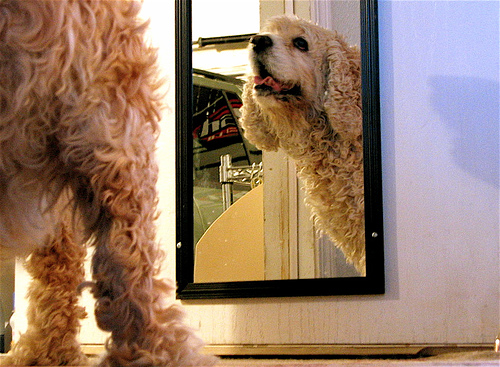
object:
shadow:
[428, 72, 500, 189]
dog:
[4, 0, 222, 367]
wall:
[409, 12, 453, 46]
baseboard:
[278, 338, 480, 364]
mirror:
[191, 0, 359, 284]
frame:
[358, 0, 387, 300]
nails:
[371, 232, 378, 238]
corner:
[252, 180, 265, 191]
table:
[203, 200, 269, 287]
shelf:
[218, 154, 265, 213]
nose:
[251, 35, 273, 54]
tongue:
[253, 75, 288, 91]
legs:
[71, 114, 208, 362]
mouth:
[252, 68, 300, 94]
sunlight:
[146, 16, 184, 96]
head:
[244, 12, 327, 121]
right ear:
[237, 75, 279, 153]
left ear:
[325, 34, 363, 145]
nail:
[177, 242, 183, 249]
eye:
[292, 36, 310, 52]